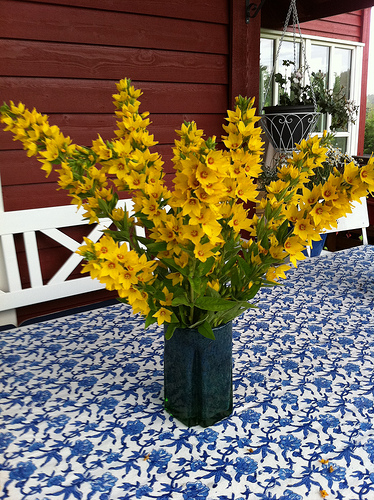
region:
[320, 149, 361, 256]
flower in a vase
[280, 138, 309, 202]
flower in a vase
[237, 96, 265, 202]
flower in a vase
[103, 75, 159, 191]
flower in a vase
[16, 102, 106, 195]
flower in a vase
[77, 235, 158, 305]
flower in a vase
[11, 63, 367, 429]
flowers on a table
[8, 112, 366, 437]
vase with flowers in it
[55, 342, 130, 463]
table cloth on a table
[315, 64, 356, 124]
plant in a pot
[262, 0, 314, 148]
chains on white basket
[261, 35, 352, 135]
four tall window panes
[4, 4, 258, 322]
red wall of building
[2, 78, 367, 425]
yellow flowers in vase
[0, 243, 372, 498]
blue and white table cloth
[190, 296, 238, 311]
green leaf of flowers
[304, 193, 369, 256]
back of white chair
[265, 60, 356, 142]
flowers in suspended pot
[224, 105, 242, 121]
yellow petals of flower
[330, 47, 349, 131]
reflection on window pane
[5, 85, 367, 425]
a flower on a table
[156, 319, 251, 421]
a black vase on a table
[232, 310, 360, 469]
a blue and white table cloth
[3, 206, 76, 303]
a white fence on the wall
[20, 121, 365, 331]
flowers in a vase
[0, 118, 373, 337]
yellow flowers in a vase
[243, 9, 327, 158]
a hanging planter from roof edge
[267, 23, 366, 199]
a window behind the planter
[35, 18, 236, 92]
red wooden siding on the house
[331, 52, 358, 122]
glass panel in the window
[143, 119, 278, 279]
flowers in the vase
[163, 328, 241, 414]
pot with flowers in it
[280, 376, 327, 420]
blue and white ground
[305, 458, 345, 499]
yellow flowers on the ground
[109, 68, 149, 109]
top of the flower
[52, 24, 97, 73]
red wall on the building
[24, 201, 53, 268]
red and white building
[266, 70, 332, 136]
pot with flowers in it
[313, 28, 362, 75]
window on the building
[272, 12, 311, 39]
ropes holding up the pot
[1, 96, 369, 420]
A vase of yellow flowers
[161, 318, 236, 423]
A blue ceramic vase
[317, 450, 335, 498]
Small flower petals on the table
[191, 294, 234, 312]
A healthy green leaf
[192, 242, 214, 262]
A yellow flower bud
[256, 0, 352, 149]
A hanging potted plant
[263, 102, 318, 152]
A black plant pot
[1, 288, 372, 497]
A blue and white designed table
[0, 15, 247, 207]
A red wooden wall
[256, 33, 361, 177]
A closed glass window